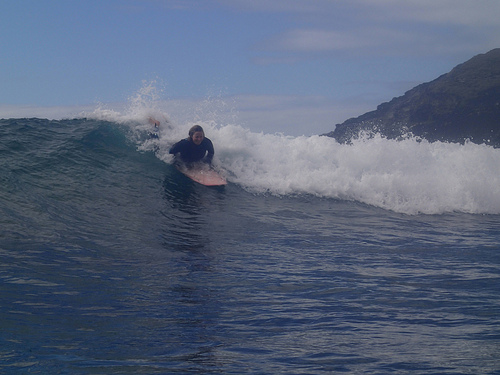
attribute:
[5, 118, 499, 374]
water — blue, dark, grey, deep blue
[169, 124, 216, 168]
surfer — woman, surfing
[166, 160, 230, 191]
surfboard — pink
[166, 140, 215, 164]
wetsuit — black, full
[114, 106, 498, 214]
wave — white, rising, splashing, cresting, crashing, foaming, tall, good, breaking, nice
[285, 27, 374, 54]
cloud — white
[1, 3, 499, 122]
sky — blue, clear, cloudy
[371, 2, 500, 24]
cloud — white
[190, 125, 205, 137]
hair — wet